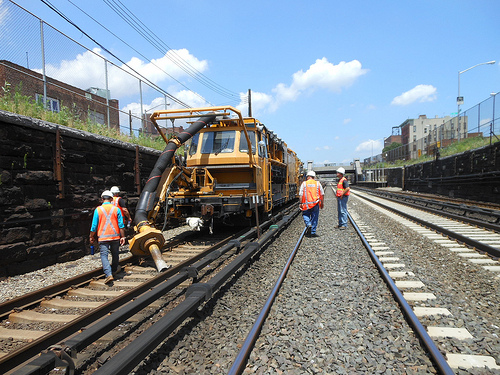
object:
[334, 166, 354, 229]
workers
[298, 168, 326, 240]
workers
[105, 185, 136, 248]
workers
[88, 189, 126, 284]
workers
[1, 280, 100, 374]
tracks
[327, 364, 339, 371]
gravel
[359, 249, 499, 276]
tracks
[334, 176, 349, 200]
vest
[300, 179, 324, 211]
vest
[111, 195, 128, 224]
vest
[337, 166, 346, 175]
hats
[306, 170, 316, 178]
hats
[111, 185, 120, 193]
hats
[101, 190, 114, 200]
hats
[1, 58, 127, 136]
building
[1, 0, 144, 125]
fence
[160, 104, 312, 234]
train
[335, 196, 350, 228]
jeans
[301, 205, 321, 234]
jeans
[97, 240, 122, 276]
jeans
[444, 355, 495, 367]
concrete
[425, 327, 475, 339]
concrete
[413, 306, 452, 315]
concrete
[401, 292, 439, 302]
concrete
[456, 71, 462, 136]
pole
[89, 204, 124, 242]
shirt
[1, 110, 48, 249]
wall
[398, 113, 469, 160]
building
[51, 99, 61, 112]
window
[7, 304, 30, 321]
ties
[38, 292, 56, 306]
ties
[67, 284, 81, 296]
ties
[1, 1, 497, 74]
sky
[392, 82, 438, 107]
clouds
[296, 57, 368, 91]
clouds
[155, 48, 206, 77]
clouds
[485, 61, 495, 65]
light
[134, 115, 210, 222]
hose